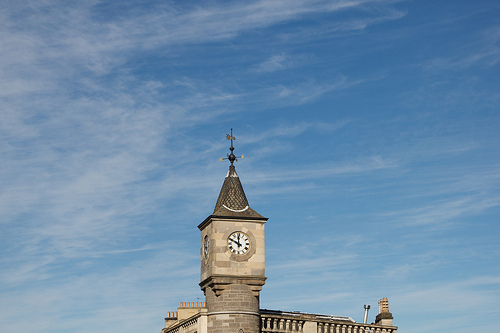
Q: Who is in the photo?
A: No one.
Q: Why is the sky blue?
A: Sunny.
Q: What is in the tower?
A: A clock.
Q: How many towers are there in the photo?
A: 1.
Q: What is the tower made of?
A: Stone.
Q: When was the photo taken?
A: Day time.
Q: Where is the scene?
A: Near the building.